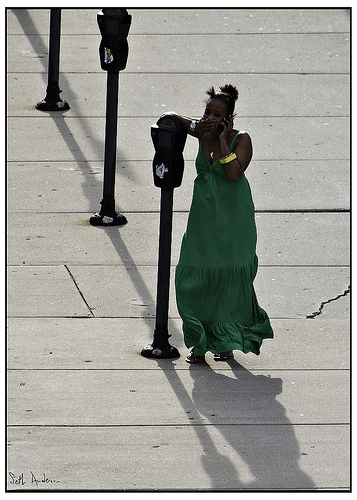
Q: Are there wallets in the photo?
A: No, there are no wallets.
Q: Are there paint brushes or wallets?
A: No, there are no wallets or paint brushes.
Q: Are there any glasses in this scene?
A: No, there are no glasses.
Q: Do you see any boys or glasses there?
A: No, there are no glasses or boys.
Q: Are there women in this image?
A: Yes, there is a woman.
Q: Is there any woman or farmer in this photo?
A: Yes, there is a woman.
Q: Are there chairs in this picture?
A: No, there are no chairs.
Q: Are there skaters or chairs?
A: No, there are no chairs or skaters.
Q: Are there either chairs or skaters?
A: No, there are no chairs or skaters.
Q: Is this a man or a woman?
A: This is a woman.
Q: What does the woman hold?
A: The woman holds the cellphone.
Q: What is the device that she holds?
A: The device is a cell phone.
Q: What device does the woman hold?
A: The woman holds the mobile phone.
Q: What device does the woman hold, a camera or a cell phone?
A: The woman holds a cell phone.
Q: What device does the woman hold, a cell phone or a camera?
A: The woman holds a cell phone.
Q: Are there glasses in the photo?
A: No, there are no glasses.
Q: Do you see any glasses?
A: No, there are no glasses.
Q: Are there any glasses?
A: No, there are no glasses.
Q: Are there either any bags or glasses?
A: No, there are no glasses or bags.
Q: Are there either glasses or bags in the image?
A: No, there are no glasses or bags.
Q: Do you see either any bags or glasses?
A: No, there are no glasses or bags.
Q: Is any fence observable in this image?
A: No, there are no fences.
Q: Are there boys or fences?
A: No, there are no fences or boys.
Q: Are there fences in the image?
A: No, there are no fences.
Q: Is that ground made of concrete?
A: Yes, the ground is made of concrete.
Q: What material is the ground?
A: The ground is made of cement.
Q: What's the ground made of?
A: The ground is made of concrete.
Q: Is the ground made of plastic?
A: No, the ground is made of cement.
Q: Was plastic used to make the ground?
A: No, the ground is made of cement.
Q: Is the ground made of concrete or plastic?
A: The ground is made of concrete.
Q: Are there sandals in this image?
A: Yes, there are sandals.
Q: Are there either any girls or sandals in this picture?
A: Yes, there are sandals.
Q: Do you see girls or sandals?
A: Yes, there are sandals.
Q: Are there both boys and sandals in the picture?
A: No, there are sandals but no boys.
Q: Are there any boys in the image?
A: No, there are no boys.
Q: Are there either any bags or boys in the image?
A: No, there are no boys or bags.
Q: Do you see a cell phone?
A: Yes, there is a cell phone.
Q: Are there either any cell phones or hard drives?
A: Yes, there is a cell phone.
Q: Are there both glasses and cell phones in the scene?
A: No, there is a cell phone but no glasses.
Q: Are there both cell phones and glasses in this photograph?
A: No, there is a cell phone but no glasses.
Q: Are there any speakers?
A: No, there are no speakers.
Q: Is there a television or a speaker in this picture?
A: No, there are no speakers or televisions.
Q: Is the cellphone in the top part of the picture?
A: Yes, the cellphone is in the top of the image.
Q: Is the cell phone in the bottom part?
A: No, the cell phone is in the top of the image.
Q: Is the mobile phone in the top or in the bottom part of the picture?
A: The mobile phone is in the top of the image.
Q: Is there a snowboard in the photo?
A: No, there are no snowboards.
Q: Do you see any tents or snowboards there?
A: No, there are no snowboards or tents.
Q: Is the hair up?
A: Yes, the hair is up.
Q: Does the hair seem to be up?
A: Yes, the hair is up.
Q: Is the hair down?
A: No, the hair is up.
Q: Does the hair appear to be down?
A: No, the hair is up.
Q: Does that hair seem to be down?
A: No, the hair is up.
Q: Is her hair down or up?
A: The hair is up.